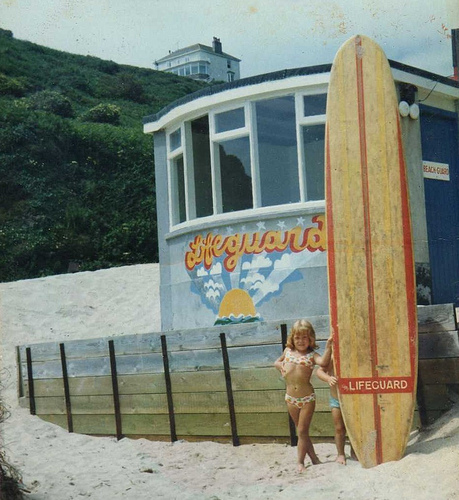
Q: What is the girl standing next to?
A: A surfboard.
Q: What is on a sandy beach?
A: A house.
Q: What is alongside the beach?
A: Sand.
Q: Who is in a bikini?
A: The girl.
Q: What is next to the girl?
A: A surfboard.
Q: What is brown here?
A: The surfboard.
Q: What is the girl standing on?
A: Sand.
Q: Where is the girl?
A: The beach.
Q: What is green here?
A: The trees.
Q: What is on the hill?
A: Sand.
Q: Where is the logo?
A: On the building.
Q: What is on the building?
A: A logo.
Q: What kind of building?
A: Lifeguard.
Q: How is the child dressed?
A: Bikini.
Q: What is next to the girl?
A: Surfboard.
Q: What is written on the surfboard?
A: Lifeguard.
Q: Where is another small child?
A: Behind the board.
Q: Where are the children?
A: Beach.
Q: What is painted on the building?
A: Sun and clouds.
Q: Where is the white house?
A: Hilltop.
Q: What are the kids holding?
A: Surfboard.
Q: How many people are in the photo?
A: Two.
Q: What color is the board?
A: Yellow and red.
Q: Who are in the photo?
A: Kids.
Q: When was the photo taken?
A: Daytime.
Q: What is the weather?
A: Sunny.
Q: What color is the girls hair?
A: Blonde.